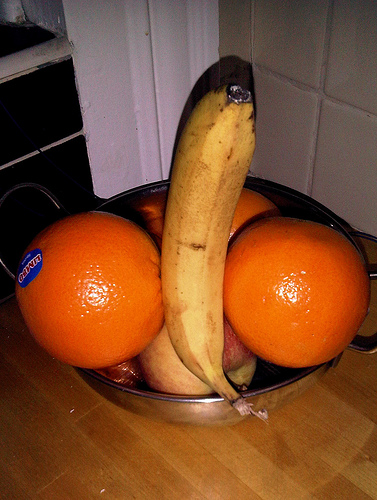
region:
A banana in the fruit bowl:
[149, 71, 256, 420]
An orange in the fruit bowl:
[215, 210, 369, 370]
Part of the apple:
[158, 359, 174, 374]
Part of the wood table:
[74, 428, 158, 474]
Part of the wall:
[308, 48, 339, 126]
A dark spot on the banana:
[223, 81, 256, 105]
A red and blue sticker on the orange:
[14, 246, 46, 290]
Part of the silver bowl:
[155, 403, 185, 417]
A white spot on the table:
[67, 404, 79, 416]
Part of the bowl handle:
[356, 343, 371, 360]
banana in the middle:
[169, 97, 258, 421]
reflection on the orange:
[83, 272, 115, 314]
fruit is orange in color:
[23, 205, 165, 359]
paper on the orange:
[21, 250, 42, 287]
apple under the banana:
[147, 343, 253, 399]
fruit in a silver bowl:
[116, 386, 317, 417]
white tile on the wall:
[259, 20, 374, 211]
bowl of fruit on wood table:
[52, 430, 372, 498]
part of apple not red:
[148, 345, 206, 393]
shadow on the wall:
[195, 61, 268, 89]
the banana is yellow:
[178, 72, 260, 393]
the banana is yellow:
[140, 107, 257, 485]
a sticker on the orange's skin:
[18, 239, 54, 291]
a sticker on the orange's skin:
[12, 247, 77, 294]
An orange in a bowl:
[224, 210, 371, 367]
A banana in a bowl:
[160, 83, 255, 416]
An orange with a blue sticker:
[15, 208, 162, 366]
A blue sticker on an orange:
[17, 247, 41, 286]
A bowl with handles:
[1, 173, 376, 425]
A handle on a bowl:
[344, 263, 376, 353]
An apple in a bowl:
[141, 312, 254, 396]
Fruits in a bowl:
[2, 78, 376, 423]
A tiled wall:
[217, 17, 375, 235]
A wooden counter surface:
[0, 236, 375, 498]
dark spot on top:
[219, 70, 252, 126]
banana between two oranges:
[175, 87, 264, 385]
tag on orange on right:
[17, 251, 50, 293]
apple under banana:
[145, 333, 259, 391]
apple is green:
[144, 342, 204, 394]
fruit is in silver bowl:
[89, 385, 334, 426]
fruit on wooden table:
[127, 425, 375, 498]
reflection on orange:
[262, 247, 315, 315]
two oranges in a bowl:
[20, 234, 343, 353]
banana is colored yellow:
[177, 90, 269, 421]